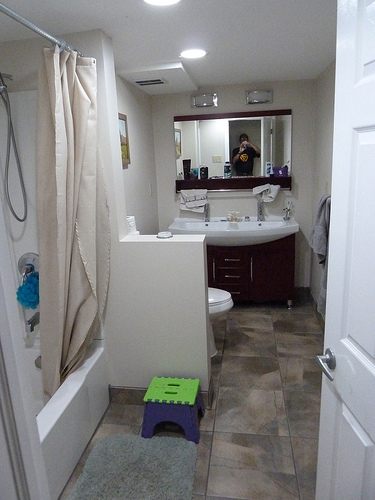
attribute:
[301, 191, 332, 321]
towel — gray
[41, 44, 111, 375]
curtain — shower, open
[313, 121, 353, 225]
door — bathroom, open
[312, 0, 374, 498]
door — white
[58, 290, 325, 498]
floor — tiled